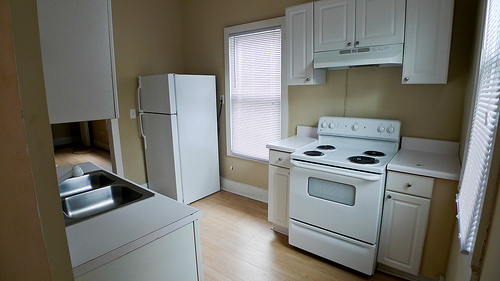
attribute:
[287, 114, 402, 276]
stove — white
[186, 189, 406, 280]
floor — wood, light colored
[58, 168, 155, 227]
sink — stainless steel, metal, double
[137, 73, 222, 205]
fridge — white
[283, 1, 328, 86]
cabinet — white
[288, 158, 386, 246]
oven — white hue, white color, white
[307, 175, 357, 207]
window — glass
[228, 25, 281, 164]
blinds — white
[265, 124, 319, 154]
counter top — white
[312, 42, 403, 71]
hood — white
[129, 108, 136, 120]
light switch — white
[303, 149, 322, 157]
burner — black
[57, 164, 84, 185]
faucet — white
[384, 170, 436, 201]
kitchen drawer — white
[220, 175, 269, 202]
trim — white